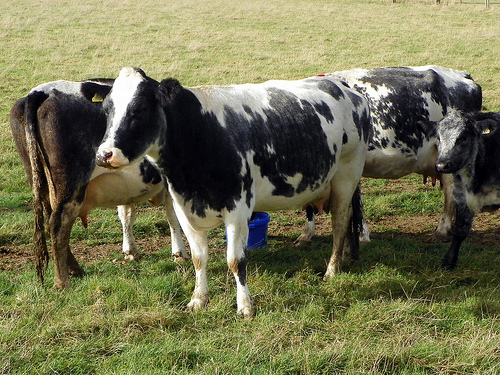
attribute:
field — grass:
[10, 319, 497, 373]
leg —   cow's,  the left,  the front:
[223, 205, 255, 318]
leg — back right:
[40, 132, 88, 285]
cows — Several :
[427, 109, 499, 274]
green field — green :
[20, 20, 480, 373]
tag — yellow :
[90, 94, 102, 106]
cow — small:
[426, 111, 498, 271]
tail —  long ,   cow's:
[20, 100, 55, 273]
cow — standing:
[434, 100, 498, 268]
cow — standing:
[308, 50, 485, 283]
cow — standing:
[6, 72, 193, 286]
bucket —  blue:
[244, 210, 272, 257]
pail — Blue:
[244, 207, 278, 255]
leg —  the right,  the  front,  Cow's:
[179, 224, 210, 314]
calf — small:
[427, 106, 498, 284]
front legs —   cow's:
[182, 220, 254, 315]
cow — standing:
[77, 65, 374, 324]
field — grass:
[7, 8, 478, 77]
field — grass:
[250, 296, 454, 374]